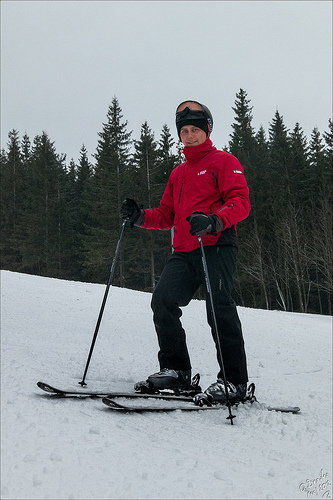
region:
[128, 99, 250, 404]
A man standing on skis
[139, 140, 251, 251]
Red jacket man is wearing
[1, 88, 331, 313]
Tall trees in the background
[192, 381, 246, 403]
Left ski boot of skier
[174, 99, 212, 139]
Brown and black hat worn by skier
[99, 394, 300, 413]
Left ski resting in the snow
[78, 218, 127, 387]
Right ski stick held by the skier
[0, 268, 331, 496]
Mountainside covered with snow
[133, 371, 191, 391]
Right snow boot of skier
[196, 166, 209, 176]
Logo on the front of the red jacket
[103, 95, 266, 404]
man looking at the camera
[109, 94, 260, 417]
a man on skiis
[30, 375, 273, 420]
a black pair of skiis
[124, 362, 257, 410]
black pair of ski shoes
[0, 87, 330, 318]
line of pine trees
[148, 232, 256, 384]
pair of black pants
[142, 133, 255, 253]
red and black ski jacket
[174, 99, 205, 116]
goggles on a man's head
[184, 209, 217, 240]
glove on a man's left hand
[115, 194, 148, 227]
glove on a man's right hand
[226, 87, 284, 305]
The tallest of the pine trees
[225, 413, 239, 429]
The bottom of the womens ski spike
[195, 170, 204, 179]
The logo on the front of the womens jacket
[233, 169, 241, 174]
The logo on the sleeve of the womens jacket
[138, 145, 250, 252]
The womens red ski jacket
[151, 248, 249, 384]
The womens black ski pants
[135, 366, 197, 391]
The womens ski boot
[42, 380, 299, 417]
The womens skis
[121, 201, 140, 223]
The womens ski gloves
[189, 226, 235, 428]
The womens ski spike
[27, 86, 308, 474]
A person getting ready to ski.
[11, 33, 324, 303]
Trees in the background.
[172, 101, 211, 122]
A pair of orange ski goggles.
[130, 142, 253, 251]
A red jacket.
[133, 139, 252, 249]
A long sleeved jacket.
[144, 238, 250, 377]
A pair of black pants.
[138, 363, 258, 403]
A pair of black ski boots.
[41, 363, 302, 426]
A pair of skis.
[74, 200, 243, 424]
A pair of ski poles.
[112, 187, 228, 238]
A pair of black gloves.